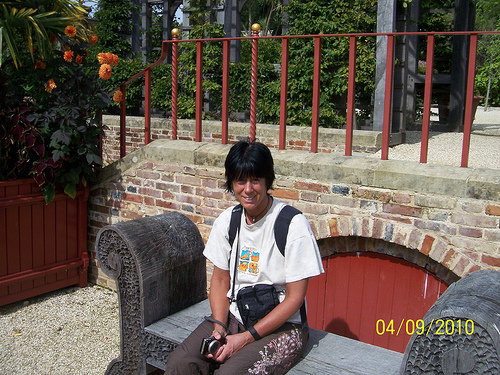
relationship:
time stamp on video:
[373, 312, 477, 338] [6, 7, 496, 367]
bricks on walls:
[394, 180, 461, 225] [98, 121, 453, 371]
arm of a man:
[202, 204, 232, 356] [163, 134, 316, 374]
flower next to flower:
[92, 61, 113, 88] [40, 76, 61, 95]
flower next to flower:
[60, 50, 76, 60] [94, 61, 115, 77]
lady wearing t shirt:
[161, 137, 330, 374] [198, 202, 325, 325]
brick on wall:
[304, 151, 366, 188] [303, 182, 401, 219]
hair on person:
[225, 141, 275, 192] [222, 140, 275, 216]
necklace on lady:
[238, 200, 276, 225] [157, 134, 331, 372]